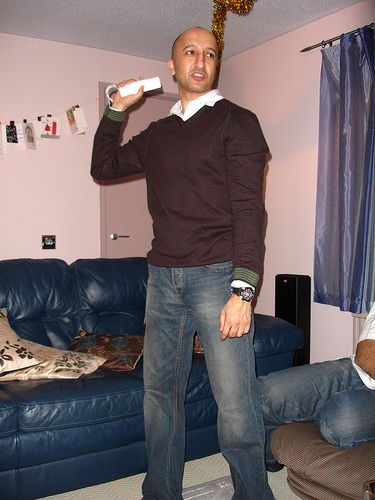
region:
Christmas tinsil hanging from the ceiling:
[202, 0, 259, 49]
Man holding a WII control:
[88, 24, 293, 499]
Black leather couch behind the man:
[0, 254, 303, 499]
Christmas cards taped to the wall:
[2, 103, 92, 154]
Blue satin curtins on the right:
[310, 24, 374, 319]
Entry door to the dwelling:
[94, 77, 195, 262]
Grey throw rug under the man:
[165, 473, 236, 499]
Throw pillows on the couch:
[2, 300, 223, 385]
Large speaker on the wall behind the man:
[273, 270, 313, 371]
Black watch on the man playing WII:
[227, 282, 258, 307]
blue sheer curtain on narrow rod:
[298, 21, 373, 311]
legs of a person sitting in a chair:
[258, 357, 372, 497]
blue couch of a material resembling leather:
[0, 256, 302, 496]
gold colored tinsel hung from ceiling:
[210, 0, 255, 54]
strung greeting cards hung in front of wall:
[1, 92, 99, 148]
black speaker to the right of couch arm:
[255, 272, 309, 364]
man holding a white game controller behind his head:
[88, 25, 215, 178]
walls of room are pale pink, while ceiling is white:
[0, 0, 371, 360]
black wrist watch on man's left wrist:
[228, 283, 252, 299]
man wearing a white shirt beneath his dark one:
[91, 89, 268, 287]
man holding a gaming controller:
[104, 75, 162, 106]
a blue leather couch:
[0, 258, 304, 497]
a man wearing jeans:
[259, 355, 373, 461]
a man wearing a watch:
[231, 284, 256, 302]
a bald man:
[166, 27, 219, 92]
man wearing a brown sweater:
[96, 97, 266, 274]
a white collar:
[169, 87, 223, 122]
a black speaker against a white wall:
[275, 270, 311, 364]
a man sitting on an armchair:
[253, 299, 374, 498]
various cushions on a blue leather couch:
[0, 305, 205, 383]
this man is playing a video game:
[81, 15, 311, 497]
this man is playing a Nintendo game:
[54, 15, 279, 495]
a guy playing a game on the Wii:
[75, 24, 310, 495]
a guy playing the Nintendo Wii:
[69, 15, 324, 495]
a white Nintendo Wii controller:
[86, 52, 176, 104]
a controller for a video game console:
[84, 45, 171, 111]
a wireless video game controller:
[90, 54, 174, 110]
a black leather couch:
[0, 255, 308, 495]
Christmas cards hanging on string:
[0, 105, 90, 150]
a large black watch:
[202, 273, 266, 307]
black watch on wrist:
[226, 277, 259, 302]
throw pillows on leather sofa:
[1, 299, 223, 380]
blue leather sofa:
[1, 255, 302, 498]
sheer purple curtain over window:
[300, 20, 373, 315]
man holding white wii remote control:
[86, 23, 275, 497]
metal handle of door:
[109, 226, 132, 245]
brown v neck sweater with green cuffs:
[88, 97, 272, 286]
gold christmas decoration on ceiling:
[205, 1, 257, 87]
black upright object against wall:
[269, 265, 313, 367]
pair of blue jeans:
[134, 259, 274, 499]